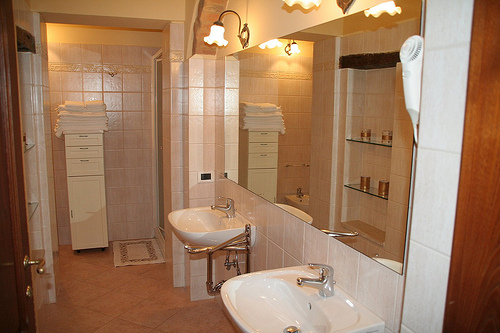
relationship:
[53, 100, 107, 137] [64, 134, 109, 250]
towels on cabinet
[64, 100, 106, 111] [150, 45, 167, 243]
towel on shower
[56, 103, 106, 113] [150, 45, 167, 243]
towel on shower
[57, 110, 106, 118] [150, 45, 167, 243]
towel on shower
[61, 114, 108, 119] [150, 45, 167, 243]
towel on shower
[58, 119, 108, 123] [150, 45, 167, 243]
towel on shower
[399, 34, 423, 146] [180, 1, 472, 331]
air freshener on wall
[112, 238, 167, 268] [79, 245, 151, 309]
rug on floor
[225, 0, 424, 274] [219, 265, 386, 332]
mirror above sink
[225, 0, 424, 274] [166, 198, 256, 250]
mirror above sink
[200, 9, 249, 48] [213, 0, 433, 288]
light above mirror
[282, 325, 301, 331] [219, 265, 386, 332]
drain in bottom of sink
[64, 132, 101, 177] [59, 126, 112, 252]
drawers on cabinet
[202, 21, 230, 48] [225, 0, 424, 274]
light above mirror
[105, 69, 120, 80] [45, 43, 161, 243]
hook on tile wall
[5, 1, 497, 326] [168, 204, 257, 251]
bathroom with sink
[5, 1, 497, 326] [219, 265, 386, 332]
bathroom with sink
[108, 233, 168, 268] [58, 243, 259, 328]
rug on floor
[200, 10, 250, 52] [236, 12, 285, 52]
light mounted to wall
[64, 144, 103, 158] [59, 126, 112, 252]
drawer in cabinet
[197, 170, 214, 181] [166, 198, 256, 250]
outlet next to sink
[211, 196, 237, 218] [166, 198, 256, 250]
faucet on sink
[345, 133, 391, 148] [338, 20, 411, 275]
shelf on wall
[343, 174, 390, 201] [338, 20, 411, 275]
shelf on wall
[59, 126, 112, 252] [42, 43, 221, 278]
cabinet against wall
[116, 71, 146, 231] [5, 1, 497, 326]
tile wall in bathroom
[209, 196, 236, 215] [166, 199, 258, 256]
faucet on basin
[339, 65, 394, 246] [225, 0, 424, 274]
reflection in mirror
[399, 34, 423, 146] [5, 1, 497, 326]
air freshener mounted in bathroom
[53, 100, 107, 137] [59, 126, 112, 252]
towels stacked on cabinet